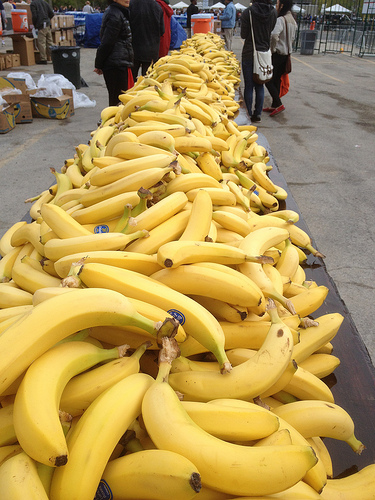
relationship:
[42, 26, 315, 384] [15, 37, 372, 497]
bananas on table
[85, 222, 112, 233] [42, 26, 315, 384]
stickers on bananas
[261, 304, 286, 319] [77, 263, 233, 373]
stem on banana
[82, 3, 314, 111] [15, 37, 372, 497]
people standing by table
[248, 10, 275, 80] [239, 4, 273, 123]
bag on person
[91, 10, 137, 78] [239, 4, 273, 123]
coat on person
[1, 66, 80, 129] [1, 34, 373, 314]
boxes on ground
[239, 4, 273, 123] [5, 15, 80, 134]
person standing by boxes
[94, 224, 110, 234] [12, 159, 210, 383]
stickers on bananas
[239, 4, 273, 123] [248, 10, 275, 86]
person carrying bag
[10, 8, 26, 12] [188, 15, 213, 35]
lid on cooler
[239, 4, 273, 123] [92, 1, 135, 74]
person wearing jacket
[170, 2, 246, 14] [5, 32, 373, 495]
tents behind bananas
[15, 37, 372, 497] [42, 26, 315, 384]
table full of bananas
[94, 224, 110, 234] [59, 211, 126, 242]
stickers on banana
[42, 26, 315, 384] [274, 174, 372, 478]
bananas are on a table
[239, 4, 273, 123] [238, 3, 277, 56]
person wearing jacket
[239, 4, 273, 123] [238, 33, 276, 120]
person wearing jeans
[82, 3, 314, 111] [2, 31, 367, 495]
people near banana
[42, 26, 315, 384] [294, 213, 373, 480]
bananas are on a table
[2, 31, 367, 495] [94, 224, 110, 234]
banana has stickers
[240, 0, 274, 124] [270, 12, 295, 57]
person wearing shirt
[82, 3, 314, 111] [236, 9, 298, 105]
people are standing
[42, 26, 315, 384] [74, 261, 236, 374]
bananas in single serve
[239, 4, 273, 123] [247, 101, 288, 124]
person wearing shoes